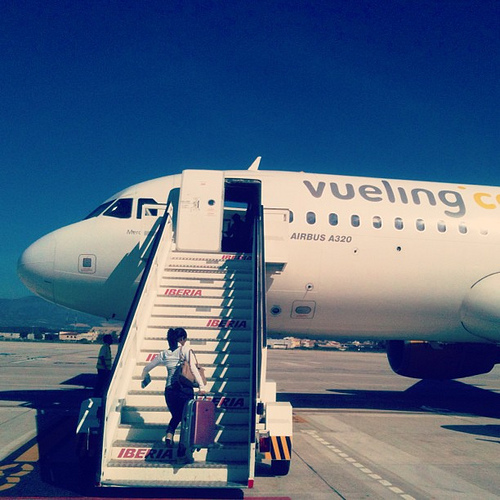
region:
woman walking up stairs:
[133, 325, 220, 460]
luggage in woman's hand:
[179, 383, 221, 455]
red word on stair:
[162, 285, 213, 303]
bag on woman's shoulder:
[171, 349, 203, 388]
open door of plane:
[213, 173, 265, 260]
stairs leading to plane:
[190, 223, 264, 337]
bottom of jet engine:
[385, 341, 486, 391]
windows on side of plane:
[333, 210, 435, 236]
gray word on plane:
[307, 181, 465, 218]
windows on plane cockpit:
[87, 188, 135, 233]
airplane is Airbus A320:
[16, 155, 498, 382]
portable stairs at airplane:
[99, 195, 264, 489]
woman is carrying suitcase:
[140, 323, 214, 463]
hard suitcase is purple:
[184, 392, 216, 448]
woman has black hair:
[165, 325, 185, 351]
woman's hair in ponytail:
[165, 327, 177, 349]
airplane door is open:
[173, 169, 261, 250]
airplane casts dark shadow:
[1, 371, 498, 442]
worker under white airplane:
[96, 333, 111, 375]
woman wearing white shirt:
[139, 341, 206, 392]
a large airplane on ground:
[57, 79, 445, 354]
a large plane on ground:
[37, 145, 392, 499]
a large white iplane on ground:
[20, 170, 495, 487]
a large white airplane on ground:
[27, 145, 498, 499]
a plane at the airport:
[35, 158, 471, 490]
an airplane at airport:
[39, 165, 444, 474]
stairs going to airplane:
[67, 174, 352, 495]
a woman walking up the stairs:
[60, 146, 343, 488]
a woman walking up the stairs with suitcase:
[82, 242, 270, 474]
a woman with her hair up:
[149, 307, 217, 414]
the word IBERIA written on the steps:
[165, 282, 214, 300]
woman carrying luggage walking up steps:
[134, 329, 223, 464]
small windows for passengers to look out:
[299, 209, 474, 240]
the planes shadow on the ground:
[286, 380, 499, 454]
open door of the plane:
[176, 168, 261, 260]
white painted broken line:
[306, 421, 429, 498]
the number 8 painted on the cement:
[1, 447, 36, 499]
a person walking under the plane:
[85, 327, 115, 401]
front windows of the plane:
[75, 187, 170, 222]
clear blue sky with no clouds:
[20, 78, 446, 151]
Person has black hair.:
[164, 318, 181, 348]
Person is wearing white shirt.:
[160, 346, 181, 369]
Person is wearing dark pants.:
[149, 396, 200, 430]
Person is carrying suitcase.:
[181, 373, 231, 453]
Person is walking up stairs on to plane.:
[142, 371, 239, 492]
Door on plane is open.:
[155, 181, 291, 260]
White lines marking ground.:
[326, 435, 378, 490]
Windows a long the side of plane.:
[293, 206, 423, 231]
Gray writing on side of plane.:
[315, 175, 416, 206]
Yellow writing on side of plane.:
[476, 184, 498, 231]